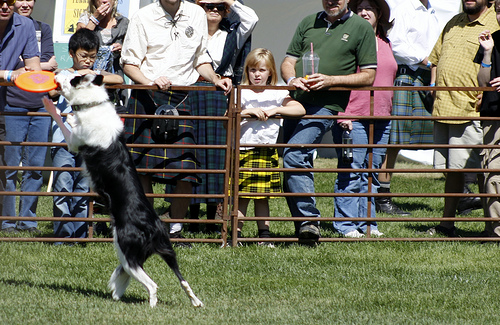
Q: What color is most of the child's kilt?
A: Yellow.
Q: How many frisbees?
A: One.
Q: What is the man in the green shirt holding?
A: A cup.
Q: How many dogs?
A: One.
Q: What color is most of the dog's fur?
A: Black.